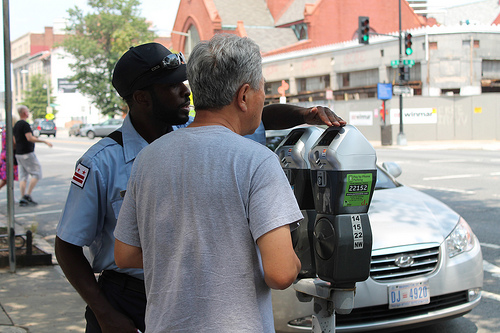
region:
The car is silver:
[251, 117, 493, 332]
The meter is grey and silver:
[275, 127, 380, 289]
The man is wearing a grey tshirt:
[114, 127, 309, 331]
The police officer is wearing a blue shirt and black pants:
[62, 117, 164, 329]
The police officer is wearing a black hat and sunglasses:
[110, 40, 188, 100]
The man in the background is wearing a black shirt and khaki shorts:
[12, 120, 42, 184]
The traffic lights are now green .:
[354, 27, 415, 62]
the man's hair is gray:
[185, 36, 265, 116]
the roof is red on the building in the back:
[30, 27, 447, 56]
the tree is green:
[65, 26, 157, 131]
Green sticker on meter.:
[346, 171, 373, 215]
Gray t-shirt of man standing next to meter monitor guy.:
[165, 131, 265, 303]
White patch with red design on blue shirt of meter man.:
[67, 158, 90, 190]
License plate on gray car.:
[389, 285, 431, 306]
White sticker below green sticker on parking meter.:
[350, 216, 370, 255]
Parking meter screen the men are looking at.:
[304, 122, 374, 170]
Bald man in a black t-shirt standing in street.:
[13, 102, 45, 207]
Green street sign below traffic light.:
[388, 54, 419, 69]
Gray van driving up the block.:
[38, 116, 59, 138]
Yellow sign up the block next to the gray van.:
[43, 106, 57, 120]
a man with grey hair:
[185, 28, 281, 138]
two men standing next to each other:
[58, 30, 319, 323]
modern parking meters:
[277, 115, 387, 282]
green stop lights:
[352, 5, 422, 85]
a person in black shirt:
[12, 104, 37, 160]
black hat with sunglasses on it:
[107, 33, 199, 92]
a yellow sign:
[41, 109, 57, 123]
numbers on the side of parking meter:
[342, 205, 370, 261]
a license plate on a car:
[384, 275, 445, 321]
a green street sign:
[385, 52, 421, 71]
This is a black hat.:
[93, 36, 200, 91]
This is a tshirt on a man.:
[112, 113, 307, 330]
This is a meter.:
[293, 112, 415, 301]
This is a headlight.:
[442, 208, 483, 261]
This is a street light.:
[399, 25, 413, 62]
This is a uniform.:
[77, 96, 274, 294]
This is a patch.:
[66, 161, 99, 184]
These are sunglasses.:
[126, 39, 193, 76]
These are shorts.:
[11, 142, 46, 216]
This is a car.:
[238, 119, 481, 329]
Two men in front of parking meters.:
[35, 5, 457, 312]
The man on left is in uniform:
[55, 47, 198, 327]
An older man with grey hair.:
[173, 35, 290, 139]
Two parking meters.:
[271, 107, 408, 292]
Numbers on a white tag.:
[348, 207, 371, 258]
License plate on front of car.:
[381, 270, 446, 315]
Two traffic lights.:
[348, 13, 438, 59]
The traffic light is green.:
[348, 5, 390, 56]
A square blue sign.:
[373, 71, 405, 106]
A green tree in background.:
[52, 0, 161, 128]